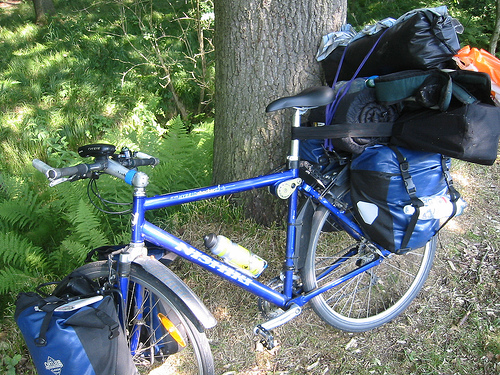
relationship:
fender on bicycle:
[93, 250, 240, 361] [19, 84, 442, 373]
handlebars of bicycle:
[29, 137, 166, 187] [19, 84, 442, 373]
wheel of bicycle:
[51, 252, 218, 373] [19, 84, 442, 373]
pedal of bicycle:
[253, 327, 287, 355] [19, 84, 442, 373]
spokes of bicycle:
[313, 227, 421, 317] [19, 84, 442, 373]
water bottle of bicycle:
[198, 231, 269, 281] [19, 84, 442, 373]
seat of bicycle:
[265, 83, 336, 113] [19, 84, 442, 373]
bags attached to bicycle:
[306, 35, 488, 238] [25, 8, 485, 373]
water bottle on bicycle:
[202, 231, 269, 281] [19, 84, 442, 373]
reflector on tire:
[146, 308, 187, 345] [20, 249, 227, 373]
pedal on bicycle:
[253, 327, 287, 355] [19, 84, 442, 373]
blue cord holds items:
[319, 23, 389, 143] [321, 15, 499, 155]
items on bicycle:
[321, 15, 499, 155] [19, 84, 442, 373]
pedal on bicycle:
[248, 323, 287, 355] [19, 84, 442, 373]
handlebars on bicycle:
[27, 135, 158, 190] [19, 84, 442, 373]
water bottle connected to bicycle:
[198, 231, 269, 281] [19, 84, 442, 373]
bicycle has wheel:
[29, 51, 463, 373] [51, 257, 218, 372]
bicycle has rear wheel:
[29, 51, 463, 373] [296, 181, 441, 335]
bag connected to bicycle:
[322, 123, 459, 285] [19, 84, 442, 373]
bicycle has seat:
[19, 84, 442, 373] [261, 87, 331, 121]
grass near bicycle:
[1, 1, 217, 370] [19, 84, 442, 373]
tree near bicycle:
[206, 4, 352, 219] [25, 8, 485, 373]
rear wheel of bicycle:
[296, 181, 448, 333] [19, 84, 442, 373]